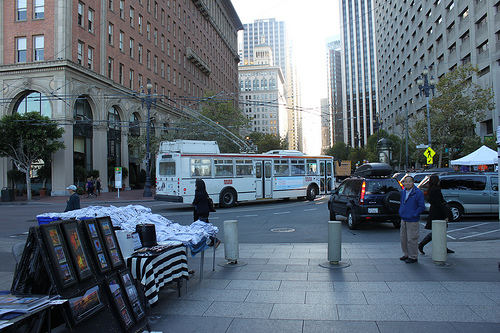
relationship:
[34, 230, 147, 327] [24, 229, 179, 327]
artwork on display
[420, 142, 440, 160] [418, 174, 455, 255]
walk sign for lady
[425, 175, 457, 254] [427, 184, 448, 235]
lady in black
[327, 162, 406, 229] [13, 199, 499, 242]
suv on street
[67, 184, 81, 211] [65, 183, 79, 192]
man wearing cap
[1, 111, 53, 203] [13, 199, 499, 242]
tree on street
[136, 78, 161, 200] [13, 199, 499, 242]
lamp post on street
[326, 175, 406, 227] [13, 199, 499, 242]
suv in street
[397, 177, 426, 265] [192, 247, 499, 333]
pedestrian on sidewalk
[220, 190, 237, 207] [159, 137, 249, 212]
tire in rear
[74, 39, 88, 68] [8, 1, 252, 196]
window on building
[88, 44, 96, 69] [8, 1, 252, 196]
window on building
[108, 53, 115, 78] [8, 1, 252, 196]
window on building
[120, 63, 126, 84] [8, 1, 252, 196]
window on building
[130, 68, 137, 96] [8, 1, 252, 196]
window on building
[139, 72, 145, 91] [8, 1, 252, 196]
window on building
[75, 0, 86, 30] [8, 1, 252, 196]
window on building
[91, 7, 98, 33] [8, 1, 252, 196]
window on building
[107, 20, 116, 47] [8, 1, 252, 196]
window on building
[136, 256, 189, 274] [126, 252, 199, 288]
part of cloth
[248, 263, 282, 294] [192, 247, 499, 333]
part of floor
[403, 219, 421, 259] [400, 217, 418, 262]
part of trouser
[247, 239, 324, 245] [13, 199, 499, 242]
edge of road